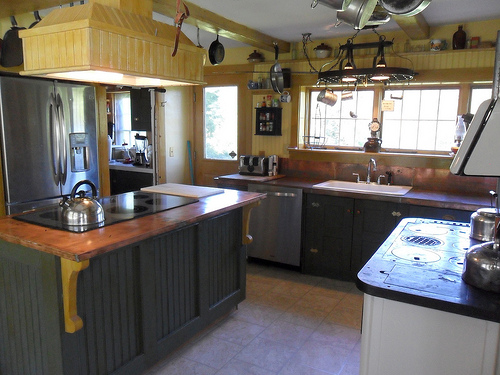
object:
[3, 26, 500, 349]
kitchen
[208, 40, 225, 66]
pans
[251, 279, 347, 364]
floor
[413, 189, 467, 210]
counter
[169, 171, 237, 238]
island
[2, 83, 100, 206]
fridge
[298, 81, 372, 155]
window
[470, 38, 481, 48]
item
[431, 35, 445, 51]
item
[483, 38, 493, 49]
item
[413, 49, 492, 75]
shelf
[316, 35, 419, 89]
pot rack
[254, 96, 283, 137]
spice rack